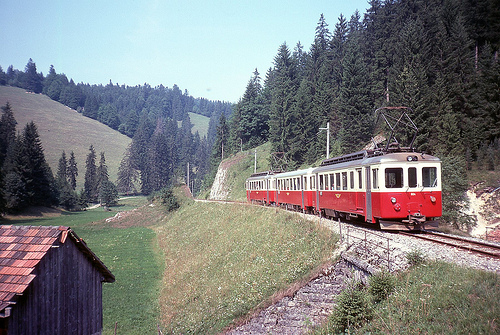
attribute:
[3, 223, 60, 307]
shingles — brown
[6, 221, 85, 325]
shingles — brown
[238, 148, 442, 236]
car — last 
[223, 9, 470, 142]
trees — tall 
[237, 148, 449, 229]
train — metal 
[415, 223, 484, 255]
tracks — train , set 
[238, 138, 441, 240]
train — red bottom 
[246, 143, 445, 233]
train — row , white, red 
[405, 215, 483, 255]
tracks — train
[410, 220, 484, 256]
tracks — side 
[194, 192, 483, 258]
track — train 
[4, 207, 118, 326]
barn — old wooden 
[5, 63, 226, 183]
mountains — background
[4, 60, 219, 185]
hillside — tall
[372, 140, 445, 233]
car — train's front 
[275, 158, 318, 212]
car — train's middle 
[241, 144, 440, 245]
train — red, white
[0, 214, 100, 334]
shack — old, wooden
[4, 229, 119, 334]
shack — wooden, small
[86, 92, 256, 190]
pine trees — large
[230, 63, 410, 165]
trees — pine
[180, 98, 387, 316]
hills — grassy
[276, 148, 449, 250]
train — red, white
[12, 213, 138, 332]
building — old, small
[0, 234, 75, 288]
roof — old, shingled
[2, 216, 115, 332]
building — small, wooden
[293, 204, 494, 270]
tracks — long, metal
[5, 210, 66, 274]
shingles — red, square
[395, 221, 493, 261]
rail — metal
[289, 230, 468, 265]
rocks — grey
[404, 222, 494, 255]
train tracks — rusty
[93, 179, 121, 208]
tree — small, green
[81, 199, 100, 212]
road — gravel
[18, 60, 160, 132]
trees — green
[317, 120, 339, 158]
pole — grey, metal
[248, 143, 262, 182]
pole — metal, grey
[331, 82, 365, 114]
leaves — green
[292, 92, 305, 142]
leaves — green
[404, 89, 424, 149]
leaves — green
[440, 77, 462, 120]
leaves — green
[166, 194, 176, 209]
leaves — green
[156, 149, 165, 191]
leaves — green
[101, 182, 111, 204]
leaves — green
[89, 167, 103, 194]
leaves — green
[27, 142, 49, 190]
leaves — green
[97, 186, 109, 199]
leaves — green